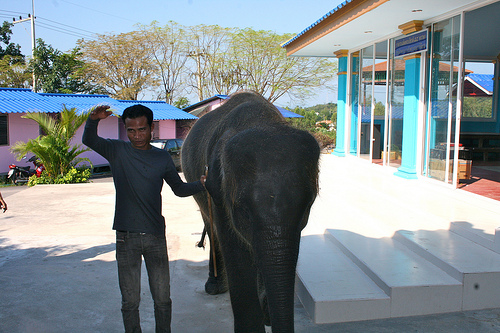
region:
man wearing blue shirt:
[90, 86, 195, 321]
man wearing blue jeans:
[100, 95, 180, 325]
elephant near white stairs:
[205, 95, 315, 330]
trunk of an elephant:
[261, 220, 301, 327]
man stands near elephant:
[95, 91, 180, 321]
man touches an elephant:
[80, 100, 215, 325]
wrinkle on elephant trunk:
[246, 216, 299, 231]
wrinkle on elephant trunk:
[256, 232, 297, 245]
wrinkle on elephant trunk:
[258, 247, 298, 261]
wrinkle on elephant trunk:
[266, 265, 298, 277]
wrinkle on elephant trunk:
[268, 283, 294, 294]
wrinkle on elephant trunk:
[273, 301, 295, 310]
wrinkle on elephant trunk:
[275, 315, 293, 325]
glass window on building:
[349, 55, 372, 157]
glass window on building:
[384, 48, 404, 168]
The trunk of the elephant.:
[263, 227, 300, 331]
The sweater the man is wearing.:
[83, 118, 201, 228]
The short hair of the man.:
[119, 103, 154, 117]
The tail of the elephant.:
[195, 223, 206, 248]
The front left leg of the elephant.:
[225, 224, 259, 329]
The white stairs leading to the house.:
[285, 163, 492, 330]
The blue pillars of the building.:
[323, 44, 434, 178]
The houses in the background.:
[7, 88, 302, 212]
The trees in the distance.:
[5, 14, 319, 108]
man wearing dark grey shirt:
[83, 97, 197, 332]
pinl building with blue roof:
[6, 84, 185, 176]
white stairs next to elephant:
[272, 149, 499, 314]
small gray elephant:
[177, 95, 322, 332]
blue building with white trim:
[285, 1, 486, 189]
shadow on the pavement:
[1, 222, 271, 332]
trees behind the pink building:
[0, 21, 343, 143]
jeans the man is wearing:
[120, 231, 177, 330]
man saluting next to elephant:
[86, 94, 214, 331]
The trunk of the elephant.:
[255, 230, 295, 331]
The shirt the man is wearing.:
[82, 117, 197, 230]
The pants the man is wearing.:
[112, 230, 172, 328]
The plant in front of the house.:
[20, 110, 91, 180]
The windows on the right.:
[340, 40, 497, 185]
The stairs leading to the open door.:
[285, 178, 490, 318]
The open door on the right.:
[455, 12, 496, 187]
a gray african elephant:
[183, 91, 322, 331]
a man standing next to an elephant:
[83, 101, 195, 330]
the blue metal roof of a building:
[3, 88, 197, 120]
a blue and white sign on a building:
[392, 30, 426, 54]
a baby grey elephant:
[177, 87, 322, 332]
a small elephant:
[177, 92, 321, 331]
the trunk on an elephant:
[249, 229, 296, 331]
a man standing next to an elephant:
[83, 102, 207, 332]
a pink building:
[0, 89, 193, 178]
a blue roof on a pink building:
[0, 84, 195, 121]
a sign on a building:
[392, 32, 429, 54]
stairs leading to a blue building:
[295, 152, 497, 323]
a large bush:
[14, 109, 85, 179]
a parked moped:
[7, 153, 45, 185]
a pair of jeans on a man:
[114, 229, 176, 331]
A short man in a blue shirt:
[94, 89, 187, 330]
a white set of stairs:
[285, 164, 497, 322]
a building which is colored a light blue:
[294, 35, 495, 194]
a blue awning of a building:
[0, 71, 208, 142]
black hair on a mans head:
[121, 102, 163, 120]